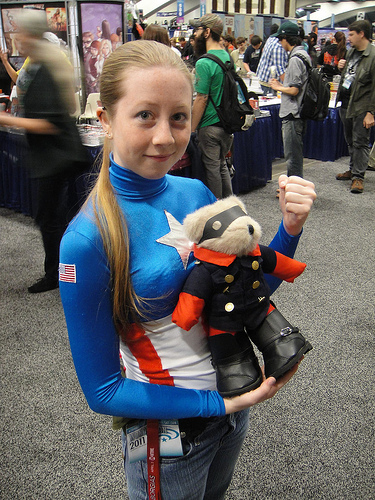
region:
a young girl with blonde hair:
[55, 38, 314, 498]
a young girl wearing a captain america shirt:
[57, 38, 315, 499]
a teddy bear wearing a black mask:
[169, 194, 313, 397]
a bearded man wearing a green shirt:
[190, 12, 233, 198]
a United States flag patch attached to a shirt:
[58, 262, 75, 282]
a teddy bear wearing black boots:
[172, 194, 310, 397]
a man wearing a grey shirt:
[269, 23, 312, 183]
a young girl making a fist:
[56, 41, 313, 498]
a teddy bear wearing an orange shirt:
[171, 193, 310, 395]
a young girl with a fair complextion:
[57, 37, 316, 497]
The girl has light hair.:
[84, 29, 209, 189]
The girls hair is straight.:
[77, 34, 202, 193]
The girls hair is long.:
[73, 33, 198, 346]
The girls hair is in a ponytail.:
[77, 32, 192, 345]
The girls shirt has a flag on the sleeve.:
[39, 246, 88, 289]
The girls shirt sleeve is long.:
[35, 217, 221, 448]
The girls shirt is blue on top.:
[58, 164, 273, 344]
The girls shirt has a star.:
[150, 200, 201, 266]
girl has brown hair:
[87, 37, 183, 344]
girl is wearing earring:
[92, 104, 115, 152]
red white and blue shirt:
[84, 153, 274, 443]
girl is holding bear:
[196, 180, 259, 406]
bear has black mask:
[208, 203, 244, 250]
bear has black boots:
[217, 310, 296, 392]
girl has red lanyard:
[138, 408, 168, 499]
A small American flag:
[54, 261, 81, 286]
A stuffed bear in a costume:
[176, 187, 306, 397]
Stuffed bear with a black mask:
[183, 191, 263, 254]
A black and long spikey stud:
[88, 104, 110, 123]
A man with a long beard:
[183, 9, 228, 63]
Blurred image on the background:
[8, 1, 73, 177]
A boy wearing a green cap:
[266, 19, 313, 52]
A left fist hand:
[268, 170, 324, 250]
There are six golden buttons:
[209, 260, 276, 314]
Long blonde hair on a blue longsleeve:
[78, 139, 154, 335]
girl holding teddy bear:
[59, 39, 318, 498]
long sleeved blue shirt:
[57, 155, 254, 418]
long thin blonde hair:
[80, 135, 159, 333]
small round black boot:
[208, 337, 264, 396]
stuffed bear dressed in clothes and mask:
[168, 194, 312, 399]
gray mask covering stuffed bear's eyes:
[198, 201, 252, 244]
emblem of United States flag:
[52, 259, 77, 285]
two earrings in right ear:
[90, 103, 114, 141]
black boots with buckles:
[200, 306, 313, 398]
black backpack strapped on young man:
[286, 51, 333, 129]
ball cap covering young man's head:
[187, 13, 226, 39]